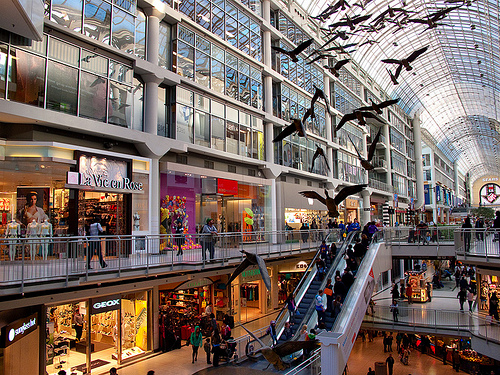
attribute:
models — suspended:
[293, 37, 395, 232]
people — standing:
[309, 219, 389, 341]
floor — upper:
[5, 232, 354, 282]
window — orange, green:
[158, 164, 269, 251]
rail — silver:
[5, 221, 330, 283]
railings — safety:
[370, 301, 496, 338]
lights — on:
[121, 298, 148, 360]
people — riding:
[316, 239, 355, 321]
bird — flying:
[353, 93, 398, 119]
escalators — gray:
[243, 223, 379, 361]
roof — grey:
[295, 0, 499, 182]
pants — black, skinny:
[190, 345, 200, 361]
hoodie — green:
[190, 325, 201, 350]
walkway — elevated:
[232, 234, 392, 371]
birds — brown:
[225, 0, 480, 366]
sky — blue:
[180, 20, 328, 110]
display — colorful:
[159, 192, 197, 251]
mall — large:
[1, 1, 498, 373]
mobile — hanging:
[262, 3, 485, 249]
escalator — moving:
[252, 187, 423, 373]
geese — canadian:
[281, 0, 473, 220]